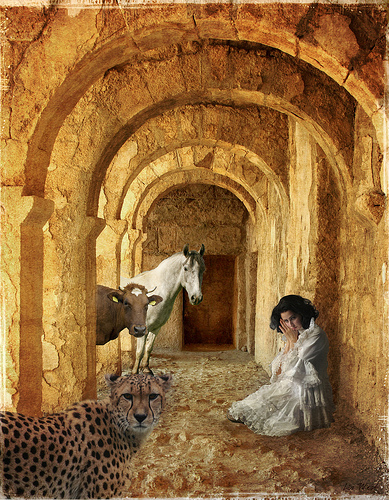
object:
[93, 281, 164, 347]
cow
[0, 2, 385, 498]
painting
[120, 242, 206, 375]
horse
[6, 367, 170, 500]
leopard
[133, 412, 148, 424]
nose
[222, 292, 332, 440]
lady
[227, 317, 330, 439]
dress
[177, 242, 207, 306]
head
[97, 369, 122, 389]
ear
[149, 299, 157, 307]
tag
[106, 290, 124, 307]
ear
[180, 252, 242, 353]
opening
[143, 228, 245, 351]
back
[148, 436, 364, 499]
dirt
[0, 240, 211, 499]
animals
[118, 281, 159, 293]
horns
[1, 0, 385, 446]
structure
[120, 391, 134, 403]
eye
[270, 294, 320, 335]
hair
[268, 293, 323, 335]
head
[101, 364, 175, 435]
head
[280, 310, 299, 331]
face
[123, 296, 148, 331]
face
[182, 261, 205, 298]
face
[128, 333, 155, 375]
legs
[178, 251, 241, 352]
door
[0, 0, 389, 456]
arches